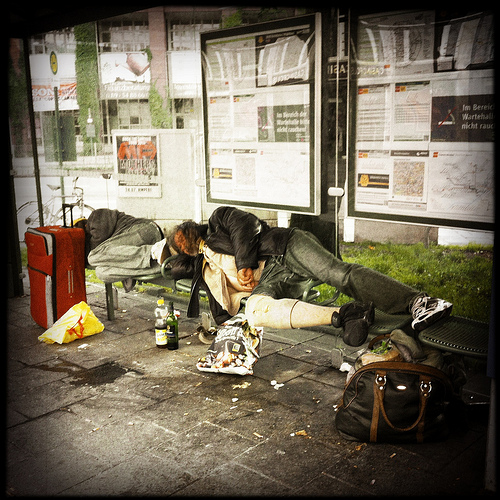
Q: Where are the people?
A: Laying on bench.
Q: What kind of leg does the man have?
A: Prosthetic.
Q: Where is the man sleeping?
A: Bus stop.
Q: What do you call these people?
A: Homeless.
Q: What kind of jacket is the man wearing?
A: Leather.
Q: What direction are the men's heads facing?
A: Left.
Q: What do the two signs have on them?
A: Maps.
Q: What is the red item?
A: Suitcase.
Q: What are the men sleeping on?
A: Benches.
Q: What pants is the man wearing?
A: Jeans.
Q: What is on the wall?
A: Posters.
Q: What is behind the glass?
A: Bushes.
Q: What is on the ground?
A: Alcohol.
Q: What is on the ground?
A: Black bag.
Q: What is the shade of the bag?
A: Black.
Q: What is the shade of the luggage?
A: Red.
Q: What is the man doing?
A: Sleeping.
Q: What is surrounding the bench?
A: Glass.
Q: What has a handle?
A: Red suitcase.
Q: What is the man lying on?
A: Bench.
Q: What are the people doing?
A: Sleeping.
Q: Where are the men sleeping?
A: Park bench.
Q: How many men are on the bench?
A: 2.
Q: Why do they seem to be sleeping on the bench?
A: Homeless.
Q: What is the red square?
A: Suitcase.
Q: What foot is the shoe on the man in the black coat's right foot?
A: Black.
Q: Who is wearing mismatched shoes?
A: Man on the right.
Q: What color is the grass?
A: Green.